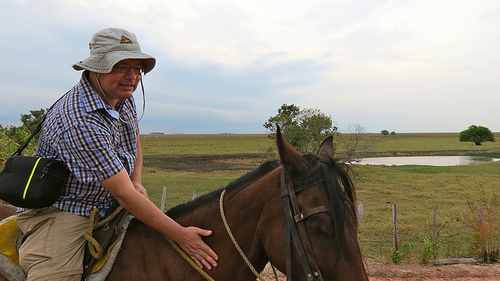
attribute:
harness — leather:
[270, 147, 356, 279]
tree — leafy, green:
[456, 122, 496, 149]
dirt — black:
[385, 255, 422, 279]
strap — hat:
[138, 79, 145, 122]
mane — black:
[139, 162, 281, 204]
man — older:
[16, 25, 222, 279]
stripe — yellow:
[18, 159, 49, 204]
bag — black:
[4, 149, 71, 211]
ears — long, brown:
[273, 123, 340, 173]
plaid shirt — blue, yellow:
[16, 69, 139, 218]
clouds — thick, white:
[309, 17, 461, 101]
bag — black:
[5, 149, 76, 209]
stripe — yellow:
[21, 156, 42, 197]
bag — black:
[0, 152, 69, 209]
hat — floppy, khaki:
[69, 26, 159, 76]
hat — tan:
[70, 22, 152, 76]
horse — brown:
[1, 122, 375, 279]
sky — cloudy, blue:
[3, 2, 496, 134]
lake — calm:
[338, 152, 498, 164]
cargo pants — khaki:
[13, 205, 103, 279]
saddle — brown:
[0, 200, 133, 279]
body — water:
[341, 151, 485, 171]